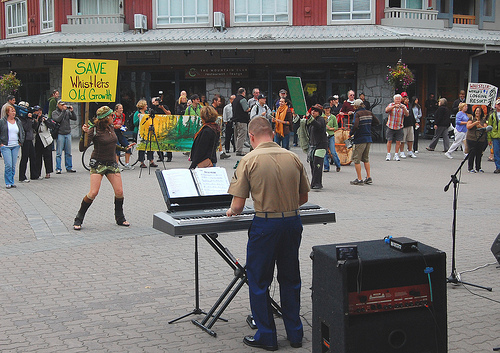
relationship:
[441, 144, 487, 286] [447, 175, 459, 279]
mic with stand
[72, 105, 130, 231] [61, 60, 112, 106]
girl holding board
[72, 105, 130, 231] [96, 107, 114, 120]
girl wearing cap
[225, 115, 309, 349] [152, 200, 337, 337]
man playing keyboard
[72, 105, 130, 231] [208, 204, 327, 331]
girl wearing pants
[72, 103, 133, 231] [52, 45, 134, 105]
girl carrying sign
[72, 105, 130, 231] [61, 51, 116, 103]
girl carrying sign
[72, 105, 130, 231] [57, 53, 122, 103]
girl carrying sign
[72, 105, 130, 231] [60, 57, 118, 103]
girl carrying board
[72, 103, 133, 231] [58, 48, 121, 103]
girl carrying sign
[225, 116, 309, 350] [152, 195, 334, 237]
man playing keyboard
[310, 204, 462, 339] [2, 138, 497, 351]
amp on sidewalk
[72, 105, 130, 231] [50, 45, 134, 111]
girl holding sign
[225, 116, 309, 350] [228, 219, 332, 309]
man wearing pants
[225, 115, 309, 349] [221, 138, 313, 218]
man wearing shirt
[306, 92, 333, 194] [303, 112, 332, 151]
woman wearing shirt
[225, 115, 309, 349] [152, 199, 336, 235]
man playing keyboard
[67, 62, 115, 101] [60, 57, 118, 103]
writing on board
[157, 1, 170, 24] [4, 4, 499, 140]
window on building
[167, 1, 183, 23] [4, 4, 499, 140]
window on building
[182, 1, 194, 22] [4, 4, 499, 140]
window on building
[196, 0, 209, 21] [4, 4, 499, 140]
window on building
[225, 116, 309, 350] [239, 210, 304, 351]
man wearing pants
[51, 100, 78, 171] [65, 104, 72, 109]
man holding camera